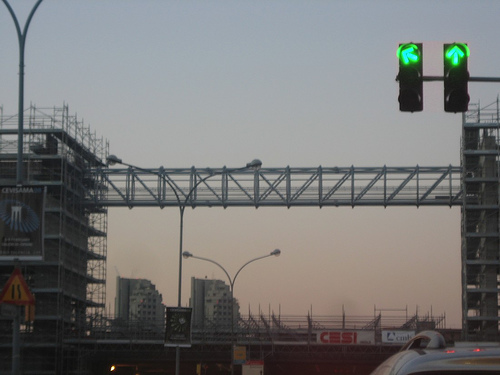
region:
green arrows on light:
[375, 17, 493, 129]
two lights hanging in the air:
[175, 230, 290, 300]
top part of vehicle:
[381, 325, 481, 370]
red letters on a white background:
[315, 321, 365, 351]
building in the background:
[117, 265, 158, 325]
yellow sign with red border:
[0, 261, 40, 306]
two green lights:
[370, 30, 486, 130]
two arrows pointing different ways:
[378, 33, 484, 122]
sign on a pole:
[1, 175, 58, 254]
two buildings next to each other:
[109, 257, 249, 335]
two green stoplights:
[374, 30, 479, 117]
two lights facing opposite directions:
[176, 230, 295, 294]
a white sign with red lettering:
[302, 332, 383, 345]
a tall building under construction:
[1, 102, 125, 332]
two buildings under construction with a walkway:
[1, 116, 496, 291]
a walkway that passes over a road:
[108, 147, 463, 248]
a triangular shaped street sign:
[0, 250, 40, 332]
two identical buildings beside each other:
[108, 262, 248, 339]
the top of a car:
[378, 324, 498, 374]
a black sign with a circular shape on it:
[156, 296, 198, 351]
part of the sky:
[256, 27, 348, 114]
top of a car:
[398, 332, 440, 367]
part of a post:
[211, 275, 247, 324]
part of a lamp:
[263, 240, 288, 269]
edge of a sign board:
[0, 283, 27, 310]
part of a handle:
[418, 319, 439, 357]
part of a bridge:
[338, 152, 389, 212]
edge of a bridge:
[286, 192, 332, 224]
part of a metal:
[253, 181, 306, 221]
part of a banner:
[315, 315, 355, 347]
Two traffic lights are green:
[395, 40, 467, 115]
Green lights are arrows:
[393, 37, 475, 72]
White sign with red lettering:
[310, 321, 375, 346]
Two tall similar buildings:
[112, 261, 248, 342]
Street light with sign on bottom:
[106, 140, 263, 365]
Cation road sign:
[0, 265, 40, 315]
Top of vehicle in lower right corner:
[340, 318, 498, 373]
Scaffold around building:
[0, 90, 126, 368]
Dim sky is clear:
[1, 16, 487, 317]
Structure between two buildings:
[78, 153, 476, 225]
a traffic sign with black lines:
[5, 261, 40, 328]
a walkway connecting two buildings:
[43, 142, 462, 222]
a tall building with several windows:
[176, 271, 246, 343]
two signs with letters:
[242, 320, 439, 360]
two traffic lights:
[349, 27, 485, 110]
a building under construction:
[13, 102, 118, 288]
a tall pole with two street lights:
[157, 231, 292, 289]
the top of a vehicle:
[386, 329, 486, 374]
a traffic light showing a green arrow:
[388, 32, 423, 116]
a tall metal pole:
[0, 14, 38, 223]